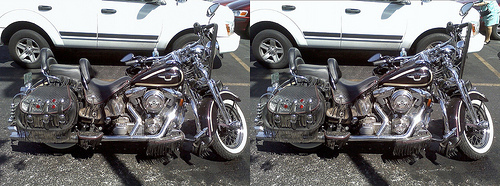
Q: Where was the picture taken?
A: A parking lot.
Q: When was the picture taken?
A: Daytime.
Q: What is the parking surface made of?
A: Asphalt.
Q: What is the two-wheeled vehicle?
A: A motorcycle.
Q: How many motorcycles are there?
A: One.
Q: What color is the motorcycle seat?
A: Black.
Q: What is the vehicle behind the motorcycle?
A: An SUV.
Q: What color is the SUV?
A: White.